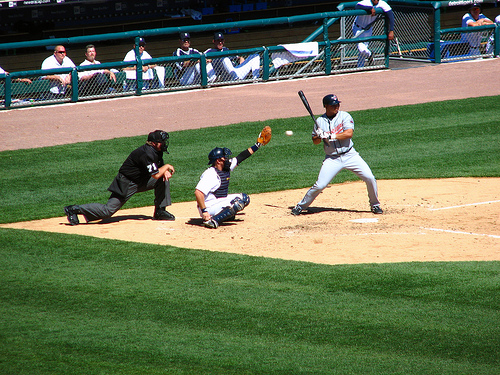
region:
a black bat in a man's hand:
[296, 90, 319, 131]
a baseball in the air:
[282, 126, 298, 140]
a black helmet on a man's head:
[321, 92, 345, 105]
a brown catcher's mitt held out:
[256, 122, 276, 149]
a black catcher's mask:
[215, 144, 235, 170]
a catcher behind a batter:
[194, 120, 275, 232]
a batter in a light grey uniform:
[290, 92, 380, 219]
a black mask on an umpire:
[154, 129, 175, 154]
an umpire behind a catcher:
[60, 127, 178, 227]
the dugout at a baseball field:
[0, 2, 497, 111]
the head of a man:
[302, 67, 358, 134]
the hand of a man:
[306, 112, 348, 154]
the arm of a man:
[320, 113, 371, 153]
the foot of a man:
[282, 192, 315, 223]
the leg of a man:
[286, 163, 350, 240]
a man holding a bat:
[298, 50, 391, 148]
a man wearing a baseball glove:
[223, 86, 310, 177]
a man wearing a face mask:
[198, 129, 252, 182]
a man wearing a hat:
[320, 71, 360, 109]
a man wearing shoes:
[270, 180, 425, 246]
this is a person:
[89, 124, 184, 232]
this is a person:
[195, 121, 269, 218]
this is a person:
[306, 85, 384, 227]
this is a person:
[39, 34, 69, 104]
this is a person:
[84, 39, 107, 94]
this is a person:
[129, 35, 162, 90]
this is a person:
[179, 17, 197, 89]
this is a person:
[211, 22, 229, 73]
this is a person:
[358, 13, 381, 66]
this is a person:
[461, 10, 498, 53]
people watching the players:
[52, 40, 277, 68]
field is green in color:
[183, 279, 293, 361]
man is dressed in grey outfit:
[299, 91, 396, 214]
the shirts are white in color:
[43, 51, 156, 74]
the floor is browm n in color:
[337, 222, 414, 252]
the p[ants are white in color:
[220, 50, 285, 92]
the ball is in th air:
[281, 115, 307, 150]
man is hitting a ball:
[271, 95, 421, 255]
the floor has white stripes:
[432, 175, 472, 245]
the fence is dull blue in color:
[171, 31, 256, 83]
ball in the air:
[276, 109, 310, 171]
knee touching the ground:
[41, 200, 109, 238]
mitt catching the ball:
[230, 118, 288, 166]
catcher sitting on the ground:
[196, 137, 251, 242]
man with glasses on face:
[38, 45, 76, 60]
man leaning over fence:
[329, 0, 391, 74]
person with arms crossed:
[453, 0, 490, 35]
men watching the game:
[31, 28, 303, 78]